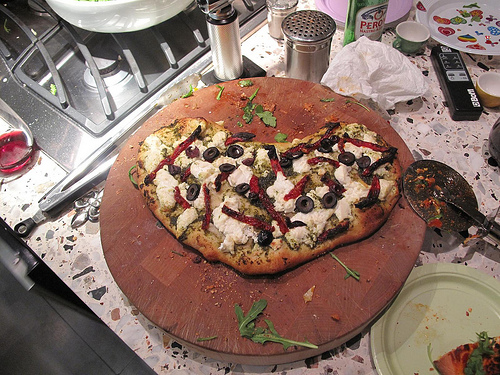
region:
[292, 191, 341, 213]
black olives on the pizza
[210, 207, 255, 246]
white cheese on the pizza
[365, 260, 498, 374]
white plate next to the pizza stone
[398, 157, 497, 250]
metal pizza cutter on the pizza stone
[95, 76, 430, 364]
brown pizza stone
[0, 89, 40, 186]
wine glass with red wine in it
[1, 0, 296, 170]
black top of a stove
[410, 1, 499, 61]
white plate with hearts on it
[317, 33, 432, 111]
white crumpled up napkin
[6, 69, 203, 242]
black and silver tongs on the counter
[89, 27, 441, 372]
a heart shaped pizza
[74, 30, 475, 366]
a pizza on a board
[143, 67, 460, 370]
a pizza on a wooden board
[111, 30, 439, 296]
a pizza with black olives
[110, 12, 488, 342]
a pizza with cheese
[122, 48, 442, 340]
a pizza with peppers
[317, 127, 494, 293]
a pizza cutter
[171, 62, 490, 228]
a pizza cuter on the board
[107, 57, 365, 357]
a cooked pizza on board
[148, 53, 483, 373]
a baked pizza on board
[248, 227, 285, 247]
black olives on top of pizza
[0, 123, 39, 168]
stemless wine glass with small amount of red wine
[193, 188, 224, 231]
red strips of pizza toppings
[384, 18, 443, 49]
small light blue coffee cup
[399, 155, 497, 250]
used pizza cutter with food on it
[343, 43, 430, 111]
crumpled white used napkin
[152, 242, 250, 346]
brown wooden pizza stone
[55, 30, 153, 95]
silver gas stove burner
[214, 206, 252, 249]
white melted cheese topping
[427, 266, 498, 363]
light green disposible paper plate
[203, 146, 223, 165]
Black olive on pizza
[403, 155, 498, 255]
Pizza cutter next to pizza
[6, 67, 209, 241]
Silver tongs next to pizza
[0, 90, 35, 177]
Glass of wine by tongs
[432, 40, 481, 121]
Black tv remote next to small green teacup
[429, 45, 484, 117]
Black tv remote next to yellow teacup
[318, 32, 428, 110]
White napkin by green teacup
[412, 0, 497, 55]
White plate with hearts next to tv remote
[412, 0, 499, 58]
White plate with hearts next to green teacup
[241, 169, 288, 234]
Red pepper on pizza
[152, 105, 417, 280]
Pizza crust is brown.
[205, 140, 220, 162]
Olive is black in color.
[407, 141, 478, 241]
Pizza cutter is dirty.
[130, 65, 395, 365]
pizza is on a wood block.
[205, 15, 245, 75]
Salt shaker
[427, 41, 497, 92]
Remote control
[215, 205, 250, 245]
White cheese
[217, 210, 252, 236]
Mozzarella cheese on pizza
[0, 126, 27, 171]
Red wine glass.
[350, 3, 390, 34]
Water bottle name is peroni.